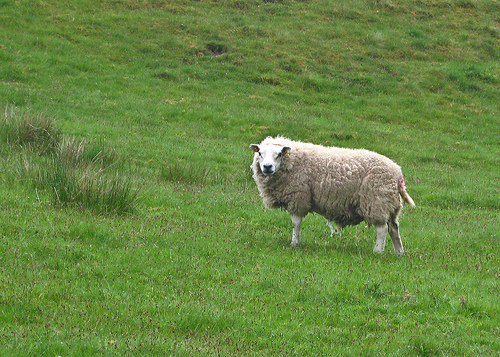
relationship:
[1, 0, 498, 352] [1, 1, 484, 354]
grass on ground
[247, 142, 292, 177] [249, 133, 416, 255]
head of animal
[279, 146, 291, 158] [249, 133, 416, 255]
left ear of animal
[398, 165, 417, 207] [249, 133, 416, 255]
tail of animal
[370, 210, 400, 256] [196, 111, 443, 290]
legs of sheep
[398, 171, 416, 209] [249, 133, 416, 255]
tail in back of animal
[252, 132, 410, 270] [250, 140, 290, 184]
ear on head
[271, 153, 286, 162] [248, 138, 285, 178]
eye on face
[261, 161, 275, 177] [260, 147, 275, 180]
nose on face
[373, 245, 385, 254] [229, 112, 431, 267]
foot on sheep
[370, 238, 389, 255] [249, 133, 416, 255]
foot on animal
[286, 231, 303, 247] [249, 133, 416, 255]
front foot on animal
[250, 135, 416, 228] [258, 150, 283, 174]
wool under face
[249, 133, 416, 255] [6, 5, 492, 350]
animal in field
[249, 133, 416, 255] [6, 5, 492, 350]
animal standing in field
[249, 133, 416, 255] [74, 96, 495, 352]
animal walking through field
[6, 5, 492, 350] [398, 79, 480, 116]
field with grass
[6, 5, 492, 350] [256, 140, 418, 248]
field with sheep